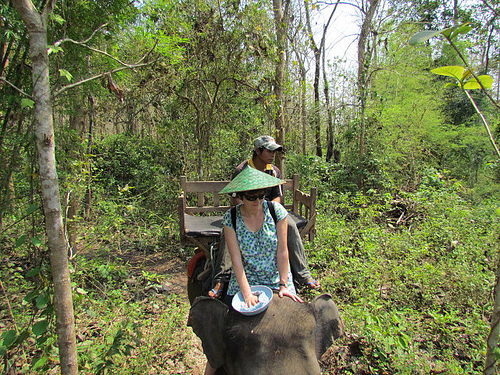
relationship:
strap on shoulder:
[230, 206, 237, 231] [219, 206, 238, 230]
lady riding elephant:
[218, 165, 304, 302] [186, 291, 343, 373]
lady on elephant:
[218, 165, 304, 302] [169, 231, 343, 373]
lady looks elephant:
[218, 165, 304, 302] [170, 237, 357, 369]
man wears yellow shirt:
[206, 133, 321, 301] [232, 141, 298, 208]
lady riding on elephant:
[218, 165, 304, 302] [186, 257, 339, 374]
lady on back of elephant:
[218, 165, 304, 302] [186, 257, 339, 374]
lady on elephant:
[218, 165, 304, 302] [182, 235, 348, 374]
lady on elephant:
[218, 165, 304, 302] [186, 291, 343, 373]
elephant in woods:
[186, 291, 343, 373] [2, 1, 496, 374]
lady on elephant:
[218, 165, 304, 302] [186, 257, 339, 374]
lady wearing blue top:
[218, 165, 304, 302] [211, 182, 333, 319]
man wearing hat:
[206, 133, 321, 301] [252, 135, 283, 152]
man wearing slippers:
[239, 141, 316, 195] [289, 256, 381, 310]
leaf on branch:
[20, 96, 34, 115] [459, 89, 498, 153]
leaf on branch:
[30, 316, 54, 335] [358, 107, 369, 159]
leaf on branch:
[2, 328, 19, 349] [55, 62, 134, 102]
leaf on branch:
[26, 263, 42, 278] [72, 14, 117, 46]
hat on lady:
[219, 164, 284, 194] [218, 165, 304, 302]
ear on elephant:
[303, 299, 359, 357] [168, 206, 363, 368]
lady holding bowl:
[218, 165, 304, 302] [232, 285, 273, 315]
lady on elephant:
[218, 165, 304, 302] [186, 248, 343, 373]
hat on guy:
[252, 133, 282, 158] [235, 129, 289, 179]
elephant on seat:
[185, 278, 344, 375] [160, 165, 320, 243]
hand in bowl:
[244, 292, 265, 310] [219, 280, 279, 314]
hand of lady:
[244, 292, 265, 310] [211, 168, 312, 315]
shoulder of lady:
[216, 205, 244, 233] [212, 159, 305, 305]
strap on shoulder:
[227, 206, 237, 227] [216, 205, 244, 233]